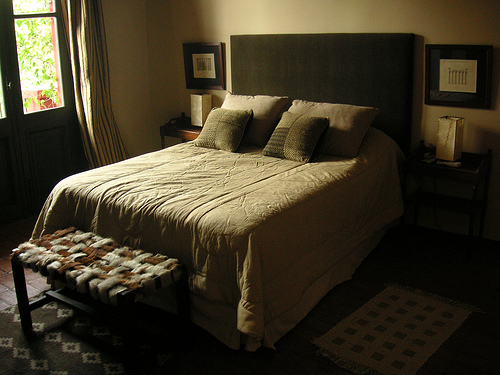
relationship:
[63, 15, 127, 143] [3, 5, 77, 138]
curtain by window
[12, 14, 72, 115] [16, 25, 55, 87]
pane showing leaves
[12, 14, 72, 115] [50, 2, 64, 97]
pane showing railing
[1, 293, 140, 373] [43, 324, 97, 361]
rug with pattern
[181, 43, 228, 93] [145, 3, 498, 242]
picture on wall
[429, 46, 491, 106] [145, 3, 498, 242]
picture on wall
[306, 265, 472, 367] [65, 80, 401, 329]
rug beside bed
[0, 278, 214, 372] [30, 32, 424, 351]
rug in front of bed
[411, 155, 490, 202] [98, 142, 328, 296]
nightstand beside bed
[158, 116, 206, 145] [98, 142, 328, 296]
nightstand beside bed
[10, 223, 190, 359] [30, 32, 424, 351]
bench in front of bed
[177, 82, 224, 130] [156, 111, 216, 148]
lamp on nightstand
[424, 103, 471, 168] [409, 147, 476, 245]
lamp on nightstand